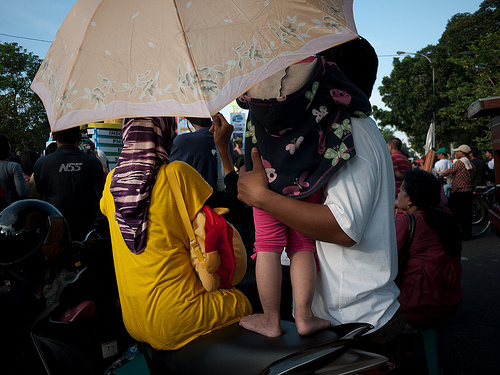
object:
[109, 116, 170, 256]
scarf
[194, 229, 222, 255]
arm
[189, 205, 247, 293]
stuffed animal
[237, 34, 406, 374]
man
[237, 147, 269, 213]
hand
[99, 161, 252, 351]
yellow shirt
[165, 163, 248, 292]
bag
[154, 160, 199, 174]
shoulder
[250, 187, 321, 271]
pants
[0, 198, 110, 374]
bike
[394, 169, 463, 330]
people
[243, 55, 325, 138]
hood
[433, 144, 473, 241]
person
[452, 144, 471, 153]
cap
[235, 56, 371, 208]
hoodie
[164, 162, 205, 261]
strap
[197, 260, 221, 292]
purse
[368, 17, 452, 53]
sky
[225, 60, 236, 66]
leaves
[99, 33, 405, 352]
family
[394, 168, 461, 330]
woman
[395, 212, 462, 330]
dress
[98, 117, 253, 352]
woman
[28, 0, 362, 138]
umbrella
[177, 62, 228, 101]
leaves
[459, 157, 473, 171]
napkin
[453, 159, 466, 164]
shoulder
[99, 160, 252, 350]
dress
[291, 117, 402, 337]
t-shirt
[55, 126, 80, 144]
hair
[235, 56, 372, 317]
child